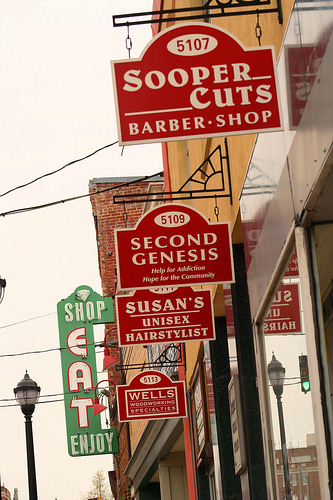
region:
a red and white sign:
[117, 368, 187, 421]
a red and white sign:
[115, 285, 212, 347]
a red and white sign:
[116, 206, 234, 288]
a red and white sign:
[111, 25, 275, 143]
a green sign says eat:
[57, 286, 119, 454]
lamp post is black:
[14, 370, 43, 499]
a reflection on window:
[262, 241, 325, 498]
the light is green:
[301, 382, 310, 391]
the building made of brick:
[88, 177, 163, 499]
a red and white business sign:
[101, 13, 287, 138]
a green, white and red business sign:
[53, 290, 127, 459]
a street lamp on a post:
[270, 353, 289, 421]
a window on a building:
[255, 217, 306, 499]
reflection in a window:
[252, 239, 321, 477]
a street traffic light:
[293, 350, 313, 393]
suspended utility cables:
[13, 170, 79, 212]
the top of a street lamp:
[14, 368, 40, 391]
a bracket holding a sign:
[111, 135, 232, 213]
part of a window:
[295, 403, 301, 410]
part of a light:
[30, 394, 39, 403]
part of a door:
[165, 464, 170, 473]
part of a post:
[145, 384, 148, 389]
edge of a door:
[170, 485, 172, 494]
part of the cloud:
[49, 437, 75, 450]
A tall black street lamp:
[11, 366, 43, 498]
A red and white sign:
[109, 20, 286, 147]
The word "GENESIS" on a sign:
[129, 245, 220, 266]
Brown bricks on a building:
[87, 175, 165, 391]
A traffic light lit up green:
[296, 353, 312, 394]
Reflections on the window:
[258, 242, 322, 498]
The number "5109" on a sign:
[157, 210, 188, 229]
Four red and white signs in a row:
[109, 19, 286, 424]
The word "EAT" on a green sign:
[64, 325, 98, 431]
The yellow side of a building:
[119, 1, 295, 457]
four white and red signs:
[92, 52, 255, 413]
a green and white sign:
[52, 282, 131, 461]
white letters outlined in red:
[63, 324, 102, 436]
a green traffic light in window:
[290, 350, 314, 399]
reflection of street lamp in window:
[263, 350, 303, 499]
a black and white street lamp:
[9, 371, 51, 495]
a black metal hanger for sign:
[107, 142, 254, 213]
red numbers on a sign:
[151, 207, 201, 228]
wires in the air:
[6, 184, 167, 433]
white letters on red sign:
[131, 228, 226, 268]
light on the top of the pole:
[10, 366, 41, 421]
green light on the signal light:
[299, 380, 312, 390]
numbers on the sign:
[168, 33, 217, 54]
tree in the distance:
[75, 468, 116, 499]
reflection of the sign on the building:
[283, 31, 330, 137]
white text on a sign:
[122, 64, 249, 91]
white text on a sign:
[126, 389, 175, 399]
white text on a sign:
[125, 399, 176, 406]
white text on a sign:
[126, 405, 174, 413]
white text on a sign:
[66, 395, 91, 424]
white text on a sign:
[66, 432, 114, 456]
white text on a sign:
[66, 324, 89, 358]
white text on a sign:
[62, 359, 94, 392]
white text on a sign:
[120, 327, 208, 341]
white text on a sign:
[134, 312, 190, 326]